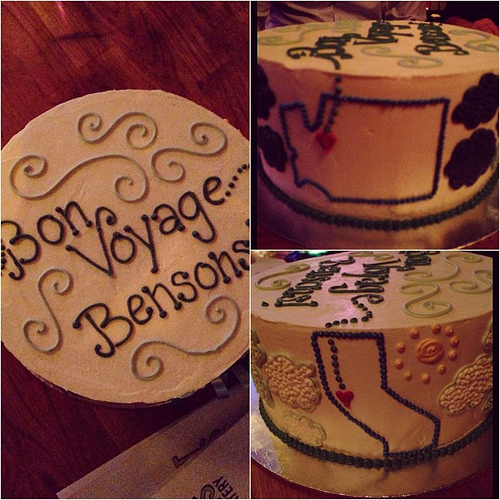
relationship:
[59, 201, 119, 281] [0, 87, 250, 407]
letter on cake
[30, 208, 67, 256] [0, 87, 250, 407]
letter on cake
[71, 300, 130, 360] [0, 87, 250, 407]
letter on cake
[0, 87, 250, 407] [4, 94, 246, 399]
cake has white frosting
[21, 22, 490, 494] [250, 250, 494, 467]
three photos of decorated cake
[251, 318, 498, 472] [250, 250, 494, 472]
decor on side of decorated cake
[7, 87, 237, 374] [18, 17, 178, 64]
cake on table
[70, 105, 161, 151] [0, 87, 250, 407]
design on cake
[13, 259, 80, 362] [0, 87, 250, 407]
design on cake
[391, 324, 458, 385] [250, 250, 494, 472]
design on decorated cake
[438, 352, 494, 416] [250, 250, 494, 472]
design on decorated cake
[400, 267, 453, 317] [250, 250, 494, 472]
design on decorated cake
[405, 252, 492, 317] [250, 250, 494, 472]
design on decorated cake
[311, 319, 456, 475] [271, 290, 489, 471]
california drawn frosting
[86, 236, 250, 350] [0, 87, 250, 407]
bensons on cake